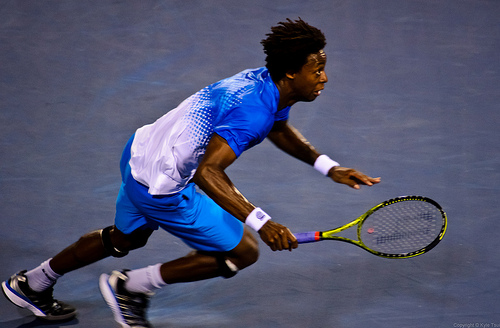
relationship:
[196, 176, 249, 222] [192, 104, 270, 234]
muscle on arm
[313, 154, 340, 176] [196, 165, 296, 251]
band on arm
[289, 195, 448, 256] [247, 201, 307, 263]
racquet in hand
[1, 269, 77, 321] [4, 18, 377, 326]
shoe on tennis player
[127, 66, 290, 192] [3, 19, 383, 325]
blue outfit on player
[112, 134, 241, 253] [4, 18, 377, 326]
shorts on tennis player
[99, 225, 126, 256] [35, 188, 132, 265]
band on calf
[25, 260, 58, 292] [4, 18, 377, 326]
sock on tennis player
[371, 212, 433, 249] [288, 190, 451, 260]
logo on racket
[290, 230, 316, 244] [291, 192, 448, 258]
handle on tennis racket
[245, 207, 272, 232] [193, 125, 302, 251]
band on arm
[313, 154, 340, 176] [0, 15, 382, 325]
band on athlete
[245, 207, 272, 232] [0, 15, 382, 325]
band on athlete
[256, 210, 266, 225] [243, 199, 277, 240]
logo on wrist band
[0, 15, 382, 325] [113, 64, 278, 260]
athlete wearing blue outfit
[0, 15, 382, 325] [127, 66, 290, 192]
athlete in blue outfit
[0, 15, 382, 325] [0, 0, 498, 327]
athlete runs across court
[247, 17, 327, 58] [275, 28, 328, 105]
hair on head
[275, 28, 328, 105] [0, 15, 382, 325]
head of athlete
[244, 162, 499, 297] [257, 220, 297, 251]
racquet in hand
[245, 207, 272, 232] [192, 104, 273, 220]
band on arm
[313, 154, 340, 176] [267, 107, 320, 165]
band on arm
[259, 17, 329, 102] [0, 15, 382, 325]
head of athlete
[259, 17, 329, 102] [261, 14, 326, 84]
head full hair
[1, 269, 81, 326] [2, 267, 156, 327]
shoe on mans feet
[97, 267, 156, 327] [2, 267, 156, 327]
shoe on mans feet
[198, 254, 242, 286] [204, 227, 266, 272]
band below knee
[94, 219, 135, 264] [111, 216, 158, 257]
band below knee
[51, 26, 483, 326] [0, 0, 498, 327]
athlete playing on court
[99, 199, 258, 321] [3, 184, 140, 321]
leg in front of leg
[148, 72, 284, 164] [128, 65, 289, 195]
checkerboard on shirt